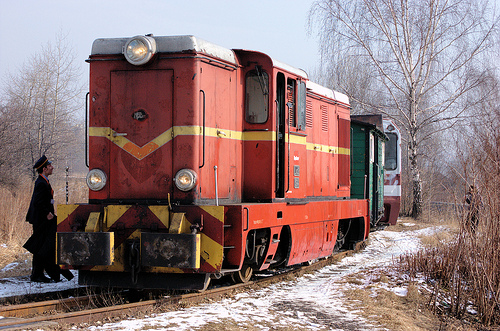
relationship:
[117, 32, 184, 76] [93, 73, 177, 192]
light on train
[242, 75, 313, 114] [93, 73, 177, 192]
window on train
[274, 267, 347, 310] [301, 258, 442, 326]
snow on ground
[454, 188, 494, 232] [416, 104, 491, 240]
person in woods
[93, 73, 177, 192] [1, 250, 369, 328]
train on rail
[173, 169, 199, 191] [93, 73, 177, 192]
headlights on train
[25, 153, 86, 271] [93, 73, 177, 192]
conductor of train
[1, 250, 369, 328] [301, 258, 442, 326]
rail on ground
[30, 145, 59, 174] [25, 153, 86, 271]
hat of conductor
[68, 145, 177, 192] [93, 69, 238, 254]
headlights on front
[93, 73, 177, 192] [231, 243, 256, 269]
train has wheel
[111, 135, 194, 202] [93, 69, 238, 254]
heart on front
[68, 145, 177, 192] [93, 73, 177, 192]
headlights on train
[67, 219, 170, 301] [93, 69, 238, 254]
stoppers on front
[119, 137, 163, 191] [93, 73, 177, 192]
heart on front train